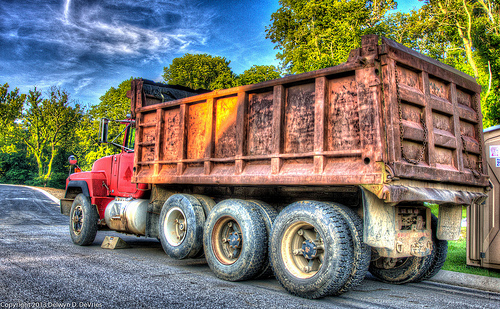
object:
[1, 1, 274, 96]
sky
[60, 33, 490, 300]
dump truck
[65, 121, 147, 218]
truck cab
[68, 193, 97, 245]
tire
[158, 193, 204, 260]
tire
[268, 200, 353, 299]
tire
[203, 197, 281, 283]
tire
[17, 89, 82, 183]
tree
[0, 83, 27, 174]
tree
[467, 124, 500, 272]
toilet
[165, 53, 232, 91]
tree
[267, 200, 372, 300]
tire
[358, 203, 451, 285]
tire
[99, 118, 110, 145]
mirror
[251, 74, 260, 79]
leaves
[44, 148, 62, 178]
trunk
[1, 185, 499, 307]
road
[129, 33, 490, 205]
bed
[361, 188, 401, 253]
flap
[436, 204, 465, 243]
flap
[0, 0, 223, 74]
clouds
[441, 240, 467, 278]
grass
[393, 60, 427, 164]
chains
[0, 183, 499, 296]
curb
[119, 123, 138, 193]
door